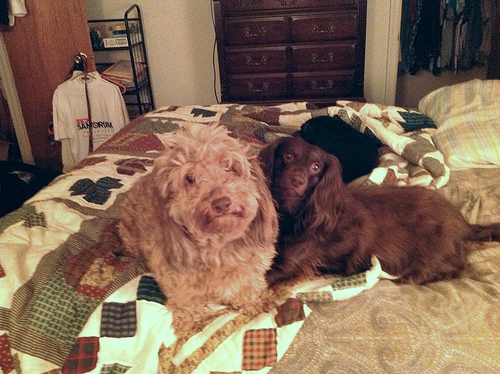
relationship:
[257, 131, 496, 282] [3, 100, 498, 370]
dog on bed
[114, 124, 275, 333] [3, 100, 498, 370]
dog on bed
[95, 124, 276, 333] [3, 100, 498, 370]
dog on bed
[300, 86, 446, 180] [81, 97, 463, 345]
quilt on bed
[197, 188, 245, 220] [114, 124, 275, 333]
nose on dog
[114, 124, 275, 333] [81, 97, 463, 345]
dog on bed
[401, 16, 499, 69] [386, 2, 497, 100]
clothes in closet